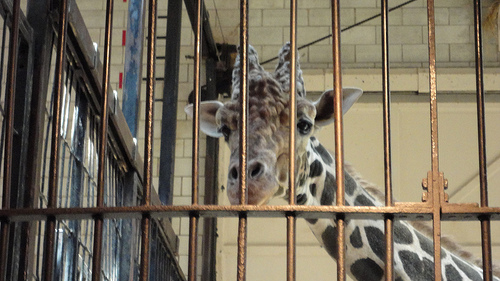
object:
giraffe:
[182, 39, 493, 280]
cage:
[1, 2, 499, 276]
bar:
[5, 201, 496, 216]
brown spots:
[247, 77, 284, 120]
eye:
[297, 113, 315, 133]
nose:
[227, 157, 269, 181]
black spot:
[363, 223, 397, 266]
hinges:
[69, 44, 104, 79]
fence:
[40, 10, 184, 276]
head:
[184, 40, 362, 216]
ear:
[311, 80, 366, 124]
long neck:
[306, 141, 479, 278]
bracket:
[389, 151, 478, 214]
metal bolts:
[420, 174, 452, 189]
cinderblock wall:
[96, 15, 480, 67]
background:
[63, 7, 500, 218]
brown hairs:
[369, 183, 380, 196]